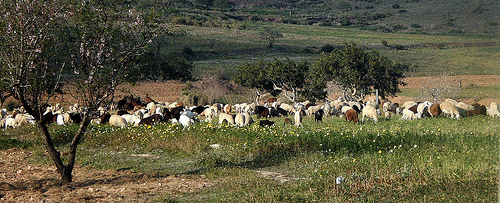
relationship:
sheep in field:
[2, 92, 499, 123] [1, 31, 500, 197]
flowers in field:
[19, 117, 461, 152] [1, 31, 500, 197]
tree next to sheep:
[11, 4, 150, 175] [2, 92, 499, 123]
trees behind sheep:
[239, 38, 390, 100] [2, 92, 499, 123]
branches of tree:
[22, 82, 98, 166] [11, 4, 150, 175]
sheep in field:
[360, 108, 383, 121] [1, 31, 500, 197]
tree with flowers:
[11, 4, 150, 175] [3, 5, 139, 91]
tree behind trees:
[261, 21, 286, 47] [239, 38, 390, 100]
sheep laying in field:
[2, 92, 499, 123] [1, 31, 500, 197]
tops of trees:
[235, 45, 401, 87] [239, 38, 390, 100]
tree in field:
[11, 4, 150, 175] [1, 31, 500, 197]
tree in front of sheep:
[11, 4, 150, 175] [2, 92, 499, 123]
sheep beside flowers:
[2, 92, 499, 123] [19, 117, 461, 152]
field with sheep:
[1, 31, 500, 197] [2, 92, 499, 123]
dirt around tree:
[1, 150, 198, 201] [11, 4, 150, 175]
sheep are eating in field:
[2, 92, 499, 123] [1, 31, 500, 197]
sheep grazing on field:
[2, 92, 499, 123] [1, 31, 500, 197]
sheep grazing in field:
[2, 92, 499, 123] [1, 31, 500, 197]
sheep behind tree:
[2, 92, 499, 123] [11, 4, 150, 175]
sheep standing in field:
[2, 92, 499, 123] [1, 31, 500, 197]